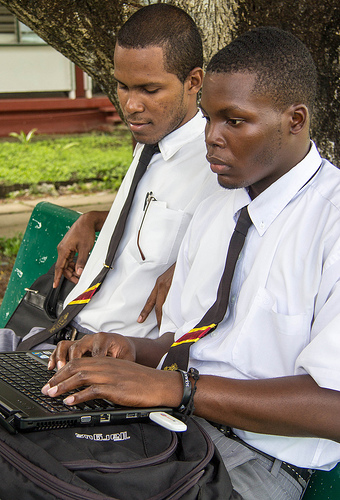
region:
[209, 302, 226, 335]
edge of a tie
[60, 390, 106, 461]
part of a laptop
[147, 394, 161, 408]
edge of a hand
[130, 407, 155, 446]
edge of a hand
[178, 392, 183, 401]
edge of a band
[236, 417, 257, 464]
part of a shprt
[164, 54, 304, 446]
this is a man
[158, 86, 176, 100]
the man is light skinned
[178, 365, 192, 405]
this is a wrist band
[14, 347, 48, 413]
this is a laptop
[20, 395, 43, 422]
the laptop is black in color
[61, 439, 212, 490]
this is a bag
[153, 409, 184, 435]
this is a flask disc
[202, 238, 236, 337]
this is a neck tie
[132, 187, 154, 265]
this is a spectacle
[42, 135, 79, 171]
this is a grass area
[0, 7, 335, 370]
TWO STUDENTS SITTING ON THE BENCH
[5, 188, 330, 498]
GREEN BENCH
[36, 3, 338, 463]
TWO STUDENTS IN WHITE SHIRT AND BLACK TIE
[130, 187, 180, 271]
READING GLASSES AND PEN IN THE POCKET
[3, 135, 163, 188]
GREEN GRASS ON THE GROUND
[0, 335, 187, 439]
BLACK LAPTOP COMPUTER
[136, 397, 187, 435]
WHITE USB DRIVE INSERTED IN THE LAPTOP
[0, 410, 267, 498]
BLACK LAPTOP BAG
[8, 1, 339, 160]
TRUNKS OF TREES BEHIND TWO MEN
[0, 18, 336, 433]
A STUDENT WORKING ON THE LAPTOP